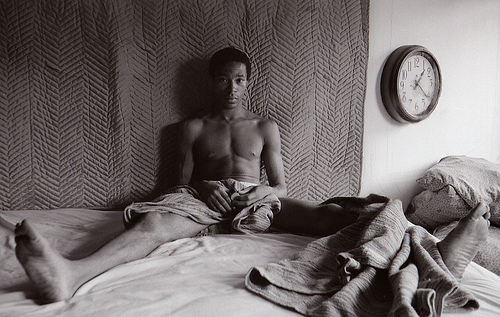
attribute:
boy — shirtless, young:
[13, 45, 363, 305]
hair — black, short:
[205, 47, 252, 82]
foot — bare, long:
[435, 200, 492, 280]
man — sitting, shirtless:
[15, 44, 494, 311]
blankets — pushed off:
[243, 192, 481, 316]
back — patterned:
[0, 1, 369, 212]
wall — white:
[357, 1, 499, 211]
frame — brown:
[380, 44, 443, 126]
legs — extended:
[78, 199, 361, 289]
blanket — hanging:
[0, 1, 369, 211]